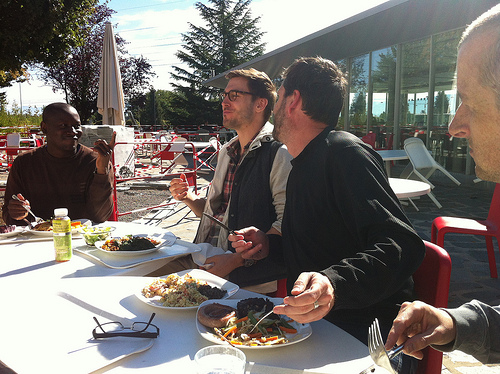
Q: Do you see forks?
A: Yes, there is a fork.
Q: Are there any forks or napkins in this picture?
A: Yes, there is a fork.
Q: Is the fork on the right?
A: Yes, the fork is on the right of the image.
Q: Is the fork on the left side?
A: No, the fork is on the right of the image.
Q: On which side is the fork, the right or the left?
A: The fork is on the right of the image.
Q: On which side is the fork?
A: The fork is on the right of the image.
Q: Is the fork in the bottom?
A: Yes, the fork is in the bottom of the image.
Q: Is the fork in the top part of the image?
A: No, the fork is in the bottom of the image.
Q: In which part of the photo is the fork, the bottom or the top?
A: The fork is in the bottom of the image.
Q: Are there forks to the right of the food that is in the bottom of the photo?
A: Yes, there is a fork to the right of the food.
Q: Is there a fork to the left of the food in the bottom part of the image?
A: No, the fork is to the right of the food.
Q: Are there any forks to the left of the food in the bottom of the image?
A: No, the fork is to the right of the food.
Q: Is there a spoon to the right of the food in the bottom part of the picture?
A: No, there is a fork to the right of the food.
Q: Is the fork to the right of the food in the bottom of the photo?
A: Yes, the fork is to the right of the food.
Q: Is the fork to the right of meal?
A: No, the fork is to the right of the food.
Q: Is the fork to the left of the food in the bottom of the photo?
A: No, the fork is to the right of the food.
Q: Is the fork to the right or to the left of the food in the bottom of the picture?
A: The fork is to the right of the food.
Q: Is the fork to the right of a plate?
A: Yes, the fork is to the right of a plate.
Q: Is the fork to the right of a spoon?
A: No, the fork is to the right of a plate.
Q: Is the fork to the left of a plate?
A: No, the fork is to the right of a plate.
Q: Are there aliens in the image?
A: No, there are no aliens.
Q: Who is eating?
A: The man is eating.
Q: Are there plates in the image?
A: Yes, there is a plate.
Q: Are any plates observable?
A: Yes, there is a plate.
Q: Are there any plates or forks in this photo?
A: Yes, there is a plate.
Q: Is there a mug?
A: No, there are no mugs.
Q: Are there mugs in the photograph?
A: No, there are no mugs.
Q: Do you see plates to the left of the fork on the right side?
A: Yes, there is a plate to the left of the fork.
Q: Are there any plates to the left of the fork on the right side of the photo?
A: Yes, there is a plate to the left of the fork.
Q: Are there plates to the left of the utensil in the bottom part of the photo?
A: Yes, there is a plate to the left of the fork.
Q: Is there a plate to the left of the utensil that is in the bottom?
A: Yes, there is a plate to the left of the fork.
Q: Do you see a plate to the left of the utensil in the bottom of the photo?
A: Yes, there is a plate to the left of the fork.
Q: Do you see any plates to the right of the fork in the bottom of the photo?
A: No, the plate is to the left of the fork.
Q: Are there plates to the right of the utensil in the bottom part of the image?
A: No, the plate is to the left of the fork.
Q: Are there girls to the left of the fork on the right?
A: No, there is a plate to the left of the fork.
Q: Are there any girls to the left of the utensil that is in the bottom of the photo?
A: No, there is a plate to the left of the fork.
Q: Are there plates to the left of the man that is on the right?
A: Yes, there is a plate to the left of the man.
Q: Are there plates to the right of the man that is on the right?
A: No, the plate is to the left of the man.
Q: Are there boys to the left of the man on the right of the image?
A: No, there is a plate to the left of the man.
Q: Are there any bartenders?
A: No, there are no bartenders.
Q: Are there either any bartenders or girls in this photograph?
A: No, there are no bartenders or girls.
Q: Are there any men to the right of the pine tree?
A: Yes, there is a man to the right of the pine tree.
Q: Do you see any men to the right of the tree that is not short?
A: Yes, there is a man to the right of the pine tree.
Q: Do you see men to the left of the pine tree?
A: No, the man is to the right of the pine tree.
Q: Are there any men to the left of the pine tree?
A: No, the man is to the right of the pine tree.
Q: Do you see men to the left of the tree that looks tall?
A: No, the man is to the right of the pine tree.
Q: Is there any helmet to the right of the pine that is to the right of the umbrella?
A: No, there is a man to the right of the pine tree.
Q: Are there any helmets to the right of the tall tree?
A: No, there is a man to the right of the pine tree.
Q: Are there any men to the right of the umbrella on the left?
A: Yes, there is a man to the right of the umbrella.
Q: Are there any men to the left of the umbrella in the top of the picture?
A: No, the man is to the right of the umbrella.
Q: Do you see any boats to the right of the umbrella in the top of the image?
A: No, there is a man to the right of the umbrella.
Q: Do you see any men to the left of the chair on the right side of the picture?
A: Yes, there is a man to the left of the chair.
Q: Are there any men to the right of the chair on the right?
A: No, the man is to the left of the chair.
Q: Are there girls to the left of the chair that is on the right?
A: No, there is a man to the left of the chair.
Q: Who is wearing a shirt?
A: The man is wearing a shirt.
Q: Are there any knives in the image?
A: Yes, there is a knife.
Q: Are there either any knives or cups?
A: Yes, there is a knife.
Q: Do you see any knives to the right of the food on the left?
A: Yes, there is a knife to the right of the food.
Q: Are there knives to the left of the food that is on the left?
A: No, the knife is to the right of the food.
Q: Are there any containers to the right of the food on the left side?
A: No, there is a knife to the right of the food.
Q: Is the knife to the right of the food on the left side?
A: Yes, the knife is to the right of the food.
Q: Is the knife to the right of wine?
A: No, the knife is to the right of the food.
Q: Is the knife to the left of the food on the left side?
A: No, the knife is to the right of the food.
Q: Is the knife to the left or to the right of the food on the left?
A: The knife is to the right of the food.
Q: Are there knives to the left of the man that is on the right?
A: Yes, there is a knife to the left of the man.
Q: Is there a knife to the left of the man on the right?
A: Yes, there is a knife to the left of the man.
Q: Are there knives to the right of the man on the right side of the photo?
A: No, the knife is to the left of the man.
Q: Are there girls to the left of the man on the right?
A: No, there is a knife to the left of the man.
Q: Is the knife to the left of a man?
A: Yes, the knife is to the left of a man.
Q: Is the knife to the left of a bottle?
A: No, the knife is to the left of a man.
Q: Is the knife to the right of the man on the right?
A: No, the knife is to the left of the man.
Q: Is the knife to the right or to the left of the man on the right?
A: The knife is to the left of the man.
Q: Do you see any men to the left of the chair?
A: Yes, there is a man to the left of the chair.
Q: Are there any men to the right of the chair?
A: No, the man is to the left of the chair.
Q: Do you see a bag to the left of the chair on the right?
A: No, there is a man to the left of the chair.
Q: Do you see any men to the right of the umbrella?
A: Yes, there is a man to the right of the umbrella.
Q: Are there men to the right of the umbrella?
A: Yes, there is a man to the right of the umbrella.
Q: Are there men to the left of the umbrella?
A: No, the man is to the right of the umbrella.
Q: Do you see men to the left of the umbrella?
A: No, the man is to the right of the umbrella.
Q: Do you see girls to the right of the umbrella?
A: No, there is a man to the right of the umbrella.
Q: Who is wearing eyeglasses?
A: The man is wearing eyeglasses.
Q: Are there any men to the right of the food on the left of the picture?
A: Yes, there is a man to the right of the food.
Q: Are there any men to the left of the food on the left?
A: No, the man is to the right of the food.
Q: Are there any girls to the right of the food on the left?
A: No, there is a man to the right of the food.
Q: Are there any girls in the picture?
A: No, there are no girls.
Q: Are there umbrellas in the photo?
A: Yes, there is an umbrella.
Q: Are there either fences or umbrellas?
A: Yes, there is an umbrella.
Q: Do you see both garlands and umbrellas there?
A: No, there is an umbrella but no garlands.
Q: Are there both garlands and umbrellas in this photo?
A: No, there is an umbrella but no garlands.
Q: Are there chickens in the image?
A: No, there are no chickens.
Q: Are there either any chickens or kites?
A: No, there are no chickens or kites.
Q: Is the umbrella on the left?
A: Yes, the umbrella is on the left of the image.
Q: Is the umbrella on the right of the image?
A: No, the umbrella is on the left of the image.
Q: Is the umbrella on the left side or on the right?
A: The umbrella is on the left of the image.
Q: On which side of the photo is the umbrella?
A: The umbrella is on the left of the image.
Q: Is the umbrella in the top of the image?
A: Yes, the umbrella is in the top of the image.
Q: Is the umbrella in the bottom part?
A: No, the umbrella is in the top of the image.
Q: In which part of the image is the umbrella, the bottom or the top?
A: The umbrella is in the top of the image.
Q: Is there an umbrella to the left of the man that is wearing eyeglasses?
A: Yes, there is an umbrella to the left of the man.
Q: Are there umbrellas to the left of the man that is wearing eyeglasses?
A: Yes, there is an umbrella to the left of the man.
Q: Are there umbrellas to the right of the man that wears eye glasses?
A: No, the umbrella is to the left of the man.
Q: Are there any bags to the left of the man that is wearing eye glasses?
A: No, there is an umbrella to the left of the man.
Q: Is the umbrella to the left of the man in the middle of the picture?
A: Yes, the umbrella is to the left of the man.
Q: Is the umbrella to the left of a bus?
A: No, the umbrella is to the left of the man.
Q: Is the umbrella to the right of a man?
A: No, the umbrella is to the left of a man.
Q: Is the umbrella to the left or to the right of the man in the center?
A: The umbrella is to the left of the man.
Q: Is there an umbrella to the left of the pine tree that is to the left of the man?
A: Yes, there is an umbrella to the left of the pine.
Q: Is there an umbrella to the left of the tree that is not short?
A: Yes, there is an umbrella to the left of the pine.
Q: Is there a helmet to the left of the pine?
A: No, there is an umbrella to the left of the pine.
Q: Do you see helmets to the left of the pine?
A: No, there is an umbrella to the left of the pine.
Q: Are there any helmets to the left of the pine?
A: No, there is an umbrella to the left of the pine.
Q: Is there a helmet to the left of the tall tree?
A: No, there is an umbrella to the left of the pine.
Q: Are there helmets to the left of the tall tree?
A: No, there is an umbrella to the left of the pine.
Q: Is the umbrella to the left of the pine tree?
A: Yes, the umbrella is to the left of the pine tree.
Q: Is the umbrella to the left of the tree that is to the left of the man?
A: Yes, the umbrella is to the left of the pine tree.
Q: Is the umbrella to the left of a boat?
A: No, the umbrella is to the left of the pine tree.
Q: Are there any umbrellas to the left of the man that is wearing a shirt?
A: Yes, there is an umbrella to the left of the man.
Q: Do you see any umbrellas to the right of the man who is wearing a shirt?
A: No, the umbrella is to the left of the man.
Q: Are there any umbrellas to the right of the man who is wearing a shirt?
A: No, the umbrella is to the left of the man.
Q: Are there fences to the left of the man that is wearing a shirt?
A: No, there is an umbrella to the left of the man.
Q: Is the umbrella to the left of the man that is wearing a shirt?
A: Yes, the umbrella is to the left of the man.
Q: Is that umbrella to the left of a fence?
A: No, the umbrella is to the left of the man.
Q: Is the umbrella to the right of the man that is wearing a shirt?
A: No, the umbrella is to the left of the man.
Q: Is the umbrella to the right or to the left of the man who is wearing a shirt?
A: The umbrella is to the left of the man.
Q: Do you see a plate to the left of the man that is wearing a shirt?
A: Yes, there are plates to the left of the man.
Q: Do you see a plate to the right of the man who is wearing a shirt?
A: No, the plates are to the left of the man.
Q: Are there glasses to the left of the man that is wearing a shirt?
A: No, there are plates to the left of the man.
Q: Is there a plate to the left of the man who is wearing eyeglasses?
A: Yes, there are plates to the left of the man.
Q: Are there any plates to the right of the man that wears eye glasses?
A: No, the plates are to the left of the man.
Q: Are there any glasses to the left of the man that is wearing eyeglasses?
A: No, there are plates to the left of the man.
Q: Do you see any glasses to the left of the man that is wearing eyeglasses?
A: No, there are plates to the left of the man.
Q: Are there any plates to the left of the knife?
A: Yes, there are plates to the left of the knife.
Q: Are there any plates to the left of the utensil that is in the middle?
A: Yes, there are plates to the left of the knife.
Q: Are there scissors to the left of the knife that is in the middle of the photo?
A: No, there are plates to the left of the knife.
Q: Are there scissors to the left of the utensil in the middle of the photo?
A: No, there are plates to the left of the knife.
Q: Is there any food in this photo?
A: Yes, there is food.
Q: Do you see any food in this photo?
A: Yes, there is food.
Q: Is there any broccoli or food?
A: Yes, there is food.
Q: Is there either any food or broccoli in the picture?
A: Yes, there is food.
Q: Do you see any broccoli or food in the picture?
A: Yes, there is food.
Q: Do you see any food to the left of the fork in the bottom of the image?
A: Yes, there is food to the left of the fork.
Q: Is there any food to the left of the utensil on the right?
A: Yes, there is food to the left of the fork.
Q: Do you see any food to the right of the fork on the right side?
A: No, the food is to the left of the fork.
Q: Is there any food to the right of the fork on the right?
A: No, the food is to the left of the fork.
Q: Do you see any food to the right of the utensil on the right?
A: No, the food is to the left of the fork.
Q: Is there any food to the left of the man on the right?
A: Yes, there is food to the left of the man.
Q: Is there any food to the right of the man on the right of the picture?
A: No, the food is to the left of the man.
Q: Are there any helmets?
A: No, there are no helmets.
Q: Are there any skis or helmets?
A: No, there are no helmets or skis.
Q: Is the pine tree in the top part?
A: Yes, the pine tree is in the top of the image.